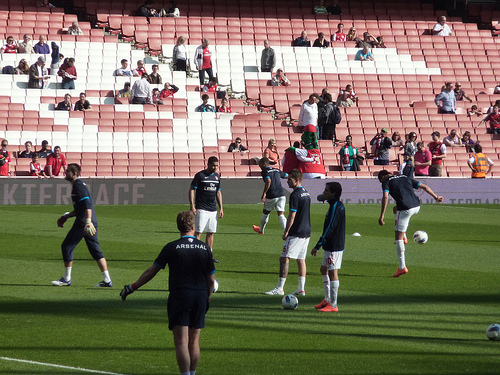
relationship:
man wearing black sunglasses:
[227, 135, 247, 152] [234, 141, 242, 144]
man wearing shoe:
[325, 180, 346, 317] [314, 295, 330, 310]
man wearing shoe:
[325, 180, 346, 317] [317, 302, 337, 313]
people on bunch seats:
[2, 18, 495, 179] [84, 41, 335, 124]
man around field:
[120, 211, 217, 374] [0, 202, 498, 373]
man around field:
[264, 168, 312, 296] [0, 202, 498, 373]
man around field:
[310, 181, 346, 313] [0, 202, 498, 373]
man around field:
[377, 170, 443, 278] [0, 202, 498, 373]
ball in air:
[413, 229, 429, 245] [405, 216, 443, 263]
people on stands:
[295, 89, 344, 150] [231, 116, 388, 162]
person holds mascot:
[442, 82, 473, 110] [433, 91, 459, 111]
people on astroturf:
[221, 170, 399, 292] [204, 297, 459, 361]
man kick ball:
[317, 179, 363, 323] [413, 229, 429, 245]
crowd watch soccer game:
[287, 25, 381, 61] [20, 150, 456, 373]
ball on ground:
[278, 292, 298, 310] [0, 203, 495, 374]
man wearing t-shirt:
[123, 211, 219, 373] [157, 236, 216, 300]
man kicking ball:
[363, 167, 445, 297] [407, 224, 428, 248]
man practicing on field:
[120, 211, 217, 374] [22, 31, 496, 373]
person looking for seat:
[193, 37, 214, 82] [217, 72, 230, 85]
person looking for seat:
[172, 33, 188, 70] [216, 58, 231, 66]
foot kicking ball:
[392, 234, 407, 246] [411, 231, 427, 246]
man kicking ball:
[377, 170, 443, 278] [411, 231, 427, 246]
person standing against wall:
[467, 144, 494, 180] [1, 172, 498, 217]